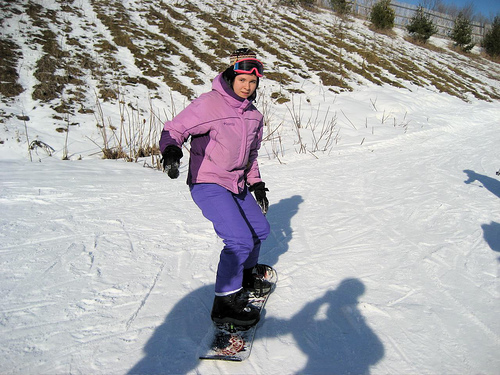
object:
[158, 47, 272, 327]
woman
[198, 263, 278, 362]
snowboard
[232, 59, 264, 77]
goggles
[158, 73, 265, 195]
coat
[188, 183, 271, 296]
snow pants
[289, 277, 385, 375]
shadow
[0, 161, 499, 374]
snow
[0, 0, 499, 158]
slope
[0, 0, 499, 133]
snow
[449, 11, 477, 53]
tree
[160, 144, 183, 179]
glove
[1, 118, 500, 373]
track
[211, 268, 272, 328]
snow boots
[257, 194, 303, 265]
shadow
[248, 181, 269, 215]
gloves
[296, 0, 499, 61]
trees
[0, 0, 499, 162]
grass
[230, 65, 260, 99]
head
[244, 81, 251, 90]
nose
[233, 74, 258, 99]
face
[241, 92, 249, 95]
lips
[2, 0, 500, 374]
ground